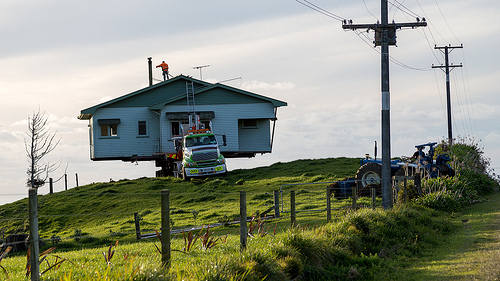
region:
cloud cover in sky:
[0, 4, 497, 196]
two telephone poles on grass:
[341, 1, 463, 211]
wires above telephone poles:
[308, 3, 468, 69]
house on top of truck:
[83, 71, 285, 180]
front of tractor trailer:
[180, 129, 227, 179]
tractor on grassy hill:
[329, 141, 440, 198]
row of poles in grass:
[0, 178, 399, 279]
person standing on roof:
[151, 60, 181, 85]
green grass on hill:
[8, 156, 358, 273]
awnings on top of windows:
[93, 108, 215, 140]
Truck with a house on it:
[80, 42, 298, 194]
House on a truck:
[80, 42, 287, 182]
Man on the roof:
[157, 57, 188, 89]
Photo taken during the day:
[10, 9, 492, 276]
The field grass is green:
[21, 177, 496, 271]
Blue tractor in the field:
[329, 141, 482, 203]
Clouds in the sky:
[0, 15, 486, 157]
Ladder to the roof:
[180, 68, 205, 135]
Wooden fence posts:
[25, 178, 400, 259]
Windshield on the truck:
[174, 136, 221, 147]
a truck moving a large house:
[77, 71, 289, 180]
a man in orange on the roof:
[151, 53, 176, 83]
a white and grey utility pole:
[336, 6, 429, 212]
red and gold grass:
[183, 222, 231, 252]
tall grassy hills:
[285, 192, 427, 279]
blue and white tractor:
[334, 140, 439, 194]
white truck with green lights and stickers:
[169, 132, 249, 182]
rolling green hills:
[82, 182, 281, 232]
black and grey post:
[134, 180, 188, 274]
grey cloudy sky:
[5, 0, 344, 62]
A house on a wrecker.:
[78, 78, 288, 168]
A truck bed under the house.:
[161, 124, 234, 179]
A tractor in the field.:
[343, 140, 386, 192]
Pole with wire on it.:
[352, 2, 424, 204]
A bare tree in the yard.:
[21, 109, 58, 199]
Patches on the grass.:
[76, 191, 148, 220]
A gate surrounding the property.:
[155, 190, 362, 233]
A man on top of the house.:
[150, 47, 176, 89]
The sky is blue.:
[59, 7, 326, 85]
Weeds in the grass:
[74, 231, 229, 261]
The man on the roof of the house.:
[156, 57, 173, 77]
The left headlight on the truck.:
[181, 154, 194, 164]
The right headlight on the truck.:
[213, 158, 222, 163]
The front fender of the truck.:
[183, 167, 225, 175]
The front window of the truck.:
[187, 138, 215, 143]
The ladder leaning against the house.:
[183, 80, 196, 117]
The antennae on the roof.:
[194, 58, 206, 77]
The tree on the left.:
[25, 108, 57, 205]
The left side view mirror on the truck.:
[172, 138, 180, 153]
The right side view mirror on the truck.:
[217, 130, 228, 148]